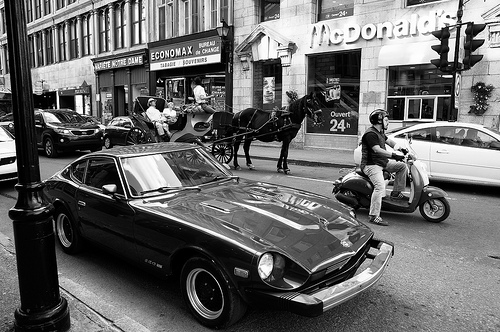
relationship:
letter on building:
[330, 27, 343, 44] [231, 0, 498, 162]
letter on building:
[343, 22, 360, 42] [231, 0, 498, 162]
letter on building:
[376, 21, 395, 41] [231, 0, 498, 162]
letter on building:
[392, 12, 420, 39] [223, 0, 496, 176]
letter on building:
[354, 18, 375, 42] [231, 0, 498, 162]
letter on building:
[180, 43, 195, 61] [0, 0, 236, 163]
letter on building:
[170, 41, 194, 69] [6, 3, 246, 172]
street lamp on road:
[196, 1, 236, 168] [5, 128, 497, 328]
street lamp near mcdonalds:
[196, 1, 236, 168] [232, 0, 497, 154]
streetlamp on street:
[0, 1, 74, 330] [2, 110, 493, 328]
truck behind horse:
[5, 103, 105, 156] [207, 83, 318, 182]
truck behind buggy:
[5, 103, 105, 156] [97, 103, 228, 159]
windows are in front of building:
[382, 66, 456, 124] [231, 0, 498, 162]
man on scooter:
[352, 114, 408, 228] [329, 146, 452, 234]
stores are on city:
[0, 1, 493, 197] [5, 5, 495, 327]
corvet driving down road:
[32, 137, 403, 327] [5, 128, 497, 328]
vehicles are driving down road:
[0, 105, 499, 324] [5, 128, 497, 328]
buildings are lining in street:
[0, 3, 498, 159] [7, 5, 497, 328]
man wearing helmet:
[352, 106, 406, 223] [362, 108, 392, 130]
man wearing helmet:
[354, 105, 399, 226] [366, 106, 386, 127]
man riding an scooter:
[356, 106, 402, 228] [331, 148, 458, 226]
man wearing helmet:
[356, 106, 402, 228] [360, 106, 390, 130]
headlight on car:
[252, 250, 278, 284] [39, 140, 393, 328]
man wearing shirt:
[134, 96, 177, 146] [140, 106, 180, 141]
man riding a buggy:
[134, 96, 177, 146] [91, 102, 242, 174]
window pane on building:
[126, 1, 142, 45] [1, 3, 484, 168]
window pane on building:
[137, 0, 147, 41] [1, 3, 484, 168]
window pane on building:
[380, 97, 407, 118] [1, 3, 484, 168]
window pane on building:
[406, 96, 423, 121] [1, 3, 484, 168]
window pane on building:
[434, 96, 453, 124] [1, 3, 484, 168]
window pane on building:
[381, 66, 455, 96] [1, 3, 484, 168]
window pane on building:
[305, 50, 359, 136] [1, 3, 484, 168]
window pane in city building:
[250, 58, 283, 113] [227, 0, 475, 136]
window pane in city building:
[69, 12, 89, 32] [0, 3, 225, 135]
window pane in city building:
[68, 14, 94, 40] [5, 6, 245, 146]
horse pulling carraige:
[227, 76, 339, 186] [107, 66, 237, 153]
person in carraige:
[181, 65, 217, 110] [149, 109, 217, 159]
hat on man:
[147, 90, 168, 108] [152, 102, 171, 127]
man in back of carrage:
[152, 102, 171, 127] [123, 59, 242, 164]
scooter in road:
[329, 146, 452, 234] [14, 110, 495, 330]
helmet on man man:
[369, 112, 390, 134] [352, 84, 425, 244]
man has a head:
[352, 84, 425, 244] [362, 87, 397, 140]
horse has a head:
[191, 70, 361, 181] [301, 69, 336, 144]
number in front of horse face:
[329, 109, 348, 149] [292, 73, 333, 135]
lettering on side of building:
[287, 0, 494, 90] [231, 0, 498, 162]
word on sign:
[136, 40, 197, 62] [138, 32, 228, 77]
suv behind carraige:
[18, 96, 132, 170] [126, 61, 223, 157]